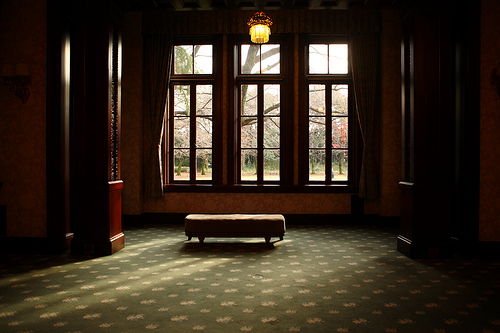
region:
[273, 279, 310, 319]
part of a floor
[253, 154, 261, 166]
part of a window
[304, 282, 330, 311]
part of a floor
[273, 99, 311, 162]
part of a stand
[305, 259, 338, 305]
part of a floor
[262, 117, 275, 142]
part of a window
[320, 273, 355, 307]
part of a floor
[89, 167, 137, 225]
part of a board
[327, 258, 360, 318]
[part of a floor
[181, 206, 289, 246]
A bench in the room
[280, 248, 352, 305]
A floor with carpet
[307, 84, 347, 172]
Glass panes in the window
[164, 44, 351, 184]
A window in the room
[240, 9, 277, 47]
Lighting in the room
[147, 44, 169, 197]
Curtains in the room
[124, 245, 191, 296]
Rays of light in the room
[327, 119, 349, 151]
Red flowers outside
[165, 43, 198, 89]
A tree in the background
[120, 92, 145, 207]
A wall in the room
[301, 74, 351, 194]
This is a window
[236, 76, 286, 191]
This is a window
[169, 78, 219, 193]
This is a window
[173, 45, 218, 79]
This is a window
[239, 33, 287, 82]
This is a window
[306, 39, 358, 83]
This is a window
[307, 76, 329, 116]
This is a window pane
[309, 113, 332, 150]
This is a window pane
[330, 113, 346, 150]
This is a window pane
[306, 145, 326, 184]
This is a window pane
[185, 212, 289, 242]
Sofa in the middle of the room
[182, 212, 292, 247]
Brown reclining sofa bench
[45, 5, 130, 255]
Dark brown polished wood pole inside home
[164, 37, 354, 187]
Windows with set of three parts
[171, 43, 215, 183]
Long rectangular clear window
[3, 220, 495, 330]
Green carpet with uniform yellow patterns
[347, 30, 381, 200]
Window curtains pulled to the right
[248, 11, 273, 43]
Bright lit yellow ceiling light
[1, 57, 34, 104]
Unlit lamp on wall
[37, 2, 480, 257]
Old classic room decor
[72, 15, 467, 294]
This room is dark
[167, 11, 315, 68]
This light is dim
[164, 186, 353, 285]
This is a place to rest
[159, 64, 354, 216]
These are windows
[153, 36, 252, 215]
Each window has 8 panels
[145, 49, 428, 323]
The room is partially lit by the sun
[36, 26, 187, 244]
This is a column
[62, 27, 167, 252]
The column is made of wood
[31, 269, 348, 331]
This is a carpet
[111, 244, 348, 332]
The carpet is green and white